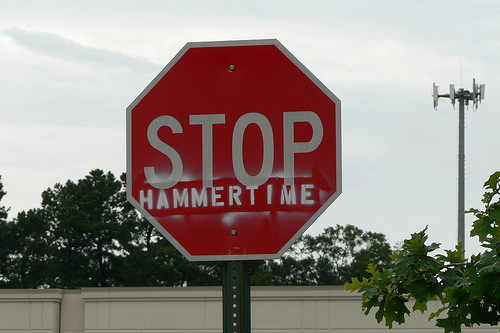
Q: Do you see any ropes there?
A: No, there are no ropes.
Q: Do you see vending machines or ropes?
A: No, there are no ropes or vending machines.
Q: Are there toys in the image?
A: No, there are no toys.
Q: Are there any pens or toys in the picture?
A: No, there are no toys or pens.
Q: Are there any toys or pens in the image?
A: No, there are no toys or pens.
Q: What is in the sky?
A: The clouds are in the sky.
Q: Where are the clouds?
A: The clouds are in the sky.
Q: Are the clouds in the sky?
A: Yes, the clouds are in the sky.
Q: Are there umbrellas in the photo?
A: No, there are no umbrellas.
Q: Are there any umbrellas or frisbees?
A: No, there are no umbrellas or frisbees.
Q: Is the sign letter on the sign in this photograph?
A: Yes, the letter is on the sign.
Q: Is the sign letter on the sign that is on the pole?
A: Yes, the letter is on the sign.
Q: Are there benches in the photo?
A: No, there are no benches.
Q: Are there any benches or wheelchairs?
A: No, there are no benches or wheelchairs.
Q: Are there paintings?
A: No, there are no paintings.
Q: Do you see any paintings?
A: No, there are no paintings.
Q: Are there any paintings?
A: No, there are no paintings.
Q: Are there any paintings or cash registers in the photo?
A: No, there are no paintings or cash registers.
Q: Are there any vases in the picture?
A: No, there are no vases.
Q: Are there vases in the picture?
A: No, there are no vases.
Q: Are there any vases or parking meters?
A: No, there are no vases or parking meters.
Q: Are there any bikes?
A: No, there are no bikes.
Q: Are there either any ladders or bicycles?
A: No, there are no bicycles or ladders.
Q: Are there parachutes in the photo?
A: No, there are no parachutes.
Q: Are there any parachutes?
A: No, there are no parachutes.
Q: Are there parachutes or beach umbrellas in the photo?
A: No, there are no parachutes or beach umbrellas.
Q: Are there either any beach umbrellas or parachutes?
A: No, there are no parachutes or beach umbrellas.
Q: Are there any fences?
A: Yes, there is a fence.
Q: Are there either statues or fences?
A: Yes, there is a fence.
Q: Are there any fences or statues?
A: Yes, there is a fence.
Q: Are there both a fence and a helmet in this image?
A: No, there is a fence but no helmets.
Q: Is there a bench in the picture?
A: No, there are no benches.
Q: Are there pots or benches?
A: No, there are no benches or pots.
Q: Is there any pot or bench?
A: No, there are no benches or pots.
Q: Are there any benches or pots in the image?
A: No, there are no benches or pots.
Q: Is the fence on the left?
A: Yes, the fence is on the left of the image.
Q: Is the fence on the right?
A: No, the fence is on the left of the image.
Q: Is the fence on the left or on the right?
A: The fence is on the left of the image.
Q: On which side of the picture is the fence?
A: The fence is on the left of the image.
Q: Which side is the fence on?
A: The fence is on the left of the image.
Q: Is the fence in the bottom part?
A: Yes, the fence is in the bottom of the image.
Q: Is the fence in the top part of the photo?
A: No, the fence is in the bottom of the image.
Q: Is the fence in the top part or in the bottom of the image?
A: The fence is in the bottom of the image.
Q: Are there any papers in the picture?
A: No, there are no papers.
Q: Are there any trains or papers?
A: No, there are no papers or trains.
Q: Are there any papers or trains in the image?
A: No, there are no papers or trains.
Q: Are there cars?
A: No, there are no cars.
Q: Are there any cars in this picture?
A: No, there are no cars.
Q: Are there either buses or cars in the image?
A: No, there are no cars or buses.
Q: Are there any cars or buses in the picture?
A: No, there are no cars or buses.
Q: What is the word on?
A: The word is on the sign.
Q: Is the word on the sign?
A: Yes, the word is on the sign.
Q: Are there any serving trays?
A: No, there are no serving trays.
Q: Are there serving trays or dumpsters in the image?
A: No, there are no serving trays or dumpsters.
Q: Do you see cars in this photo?
A: No, there are no cars.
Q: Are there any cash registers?
A: No, there are no cash registers.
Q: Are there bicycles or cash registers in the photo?
A: No, there are no cash registers or bicycles.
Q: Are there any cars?
A: No, there are no cars.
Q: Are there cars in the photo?
A: No, there are no cars.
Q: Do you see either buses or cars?
A: No, there are no cars or buses.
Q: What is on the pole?
A: The sign is on the pole.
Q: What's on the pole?
A: The sign is on the pole.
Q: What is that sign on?
A: The sign is on the pole.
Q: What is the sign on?
A: The sign is on the pole.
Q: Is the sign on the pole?
A: Yes, the sign is on the pole.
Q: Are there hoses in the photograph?
A: No, there are no hoses.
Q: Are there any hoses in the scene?
A: No, there are no hoses.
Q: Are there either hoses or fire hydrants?
A: No, there are no hoses or fire hydrants.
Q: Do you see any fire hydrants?
A: No, there are no fire hydrants.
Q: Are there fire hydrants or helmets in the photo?
A: No, there are no fire hydrants or helmets.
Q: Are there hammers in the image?
A: No, there are no hammers.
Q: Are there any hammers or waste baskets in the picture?
A: No, there are no hammers or waste baskets.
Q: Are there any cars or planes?
A: No, there are no cars or planes.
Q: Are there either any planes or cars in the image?
A: No, there are no cars or planes.